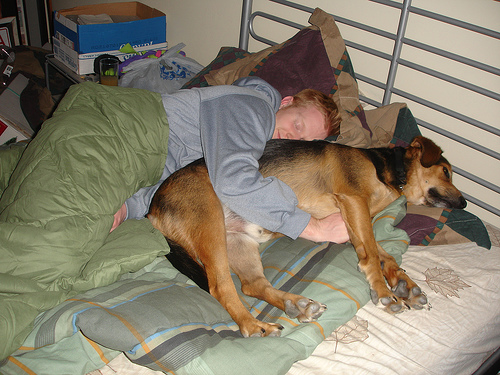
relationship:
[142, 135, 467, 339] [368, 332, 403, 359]
dog lying in bed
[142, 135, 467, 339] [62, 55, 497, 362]
dog on bed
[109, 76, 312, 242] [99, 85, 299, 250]
hoodie wearing hoodie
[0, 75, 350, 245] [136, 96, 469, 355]
guy holding dog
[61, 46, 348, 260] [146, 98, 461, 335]
guy sleeping with dog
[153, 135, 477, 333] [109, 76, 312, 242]
dog sleeping with hoodie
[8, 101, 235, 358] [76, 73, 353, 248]
blanket covering man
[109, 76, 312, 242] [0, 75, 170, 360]
hoodie under blanket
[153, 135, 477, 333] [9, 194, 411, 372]
dog on blanket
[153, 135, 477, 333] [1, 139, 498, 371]
dog on bed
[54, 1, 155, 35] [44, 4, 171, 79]
stuff inside box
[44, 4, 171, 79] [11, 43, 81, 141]
box on top of table